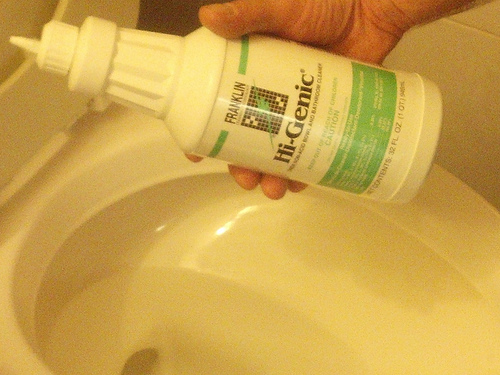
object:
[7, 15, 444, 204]
bottle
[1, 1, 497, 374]
toilet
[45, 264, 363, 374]
water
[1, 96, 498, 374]
toilet bowl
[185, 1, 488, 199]
hand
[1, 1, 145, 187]
toilet seat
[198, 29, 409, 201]
label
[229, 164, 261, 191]
finger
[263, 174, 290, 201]
finger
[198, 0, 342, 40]
thumb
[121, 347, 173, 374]
drain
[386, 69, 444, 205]
bottom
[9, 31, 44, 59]
tip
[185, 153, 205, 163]
finger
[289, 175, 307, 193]
finger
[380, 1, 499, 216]
wall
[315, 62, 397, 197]
block area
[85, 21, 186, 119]
neck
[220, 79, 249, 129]
word franklin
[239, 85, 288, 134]
grid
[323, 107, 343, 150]
caution